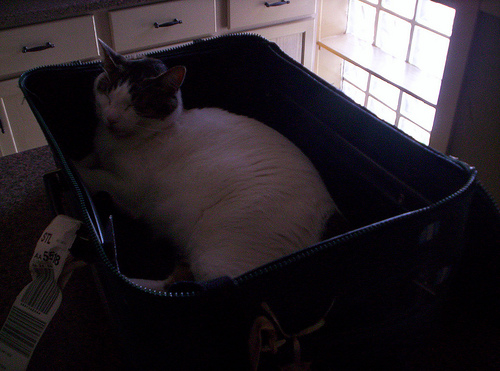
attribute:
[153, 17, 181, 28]
handle — black 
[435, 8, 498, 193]
wall — white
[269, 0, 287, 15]
handle — black 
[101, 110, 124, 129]
nose — tiny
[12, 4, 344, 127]
drawers —  white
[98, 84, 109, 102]
eye — closed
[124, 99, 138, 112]
eye — closed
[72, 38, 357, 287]
cat — white and black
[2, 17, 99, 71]
drawer — white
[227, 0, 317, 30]
drawer — white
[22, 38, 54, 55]
handle — small, black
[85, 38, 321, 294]
cat — white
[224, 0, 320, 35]
drawer — white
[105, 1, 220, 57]
drawer — white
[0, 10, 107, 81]
drawer — white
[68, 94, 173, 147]
whiskers — long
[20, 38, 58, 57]
handle — black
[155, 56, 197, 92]
cat ear —  black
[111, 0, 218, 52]
drawer — white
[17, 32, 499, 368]
black suitcase —  black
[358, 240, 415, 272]
side — blue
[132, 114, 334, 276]
fur — white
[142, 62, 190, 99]
ear — pointy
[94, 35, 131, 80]
ear — pointy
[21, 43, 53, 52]
handle — black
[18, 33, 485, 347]
container — plastic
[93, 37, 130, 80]
ears — perked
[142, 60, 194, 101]
ears — perked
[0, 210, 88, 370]
paper — white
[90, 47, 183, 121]
patch — dark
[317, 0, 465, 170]
panels — rectangular